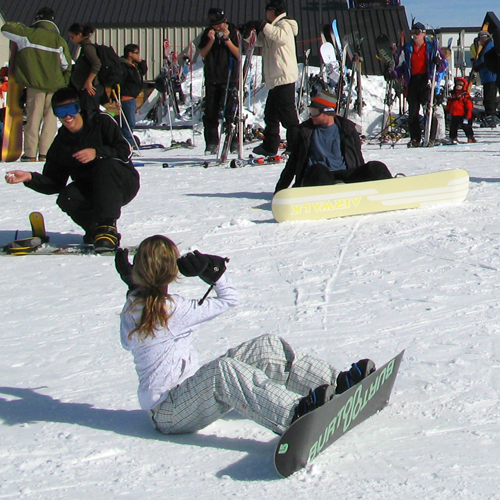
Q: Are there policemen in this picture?
A: No, there are no policemen.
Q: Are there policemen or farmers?
A: No, there are no policemen or farmers.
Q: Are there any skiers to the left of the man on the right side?
A: Yes, there is a skier to the left of the man.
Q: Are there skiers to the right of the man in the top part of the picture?
A: No, the skier is to the left of the man.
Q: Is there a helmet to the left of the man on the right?
A: No, there is a skier to the left of the man.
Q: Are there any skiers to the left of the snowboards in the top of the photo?
A: Yes, there is a skier to the left of the snowboards.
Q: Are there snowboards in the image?
A: Yes, there is a snowboard.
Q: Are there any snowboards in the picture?
A: Yes, there is a snowboard.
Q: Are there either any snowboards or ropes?
A: Yes, there is a snowboard.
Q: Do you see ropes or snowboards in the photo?
A: Yes, there is a snowboard.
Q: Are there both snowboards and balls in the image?
A: No, there is a snowboard but no balls.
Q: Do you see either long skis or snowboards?
A: Yes, there is a long snowboard.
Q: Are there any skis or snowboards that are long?
A: Yes, the snowboard is long.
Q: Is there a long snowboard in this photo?
A: Yes, there is a long snowboard.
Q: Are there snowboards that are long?
A: Yes, there is a snowboard that is long.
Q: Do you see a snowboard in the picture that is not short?
A: Yes, there is a long snowboard.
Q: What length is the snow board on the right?
A: The snowboard is long.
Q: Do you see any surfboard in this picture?
A: No, there are no surfboards.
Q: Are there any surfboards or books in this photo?
A: No, there are no surfboards or books.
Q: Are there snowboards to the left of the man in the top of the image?
A: Yes, there are snowboards to the left of the man.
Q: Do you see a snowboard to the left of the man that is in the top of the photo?
A: Yes, there are snowboards to the left of the man.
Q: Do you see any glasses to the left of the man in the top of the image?
A: No, there are snowboards to the left of the man.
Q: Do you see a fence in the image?
A: No, there are no fences.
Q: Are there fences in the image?
A: No, there are no fences.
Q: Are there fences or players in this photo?
A: No, there are no fences or players.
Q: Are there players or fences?
A: No, there are no fences or players.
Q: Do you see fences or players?
A: No, there are no fences or players.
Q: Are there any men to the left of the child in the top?
A: Yes, there is a man to the left of the child.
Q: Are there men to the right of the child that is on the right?
A: No, the man is to the left of the child.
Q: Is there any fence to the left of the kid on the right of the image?
A: No, there is a man to the left of the kid.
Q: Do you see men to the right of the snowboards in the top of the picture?
A: Yes, there is a man to the right of the snowboards.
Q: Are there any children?
A: Yes, there is a child.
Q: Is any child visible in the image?
A: Yes, there is a child.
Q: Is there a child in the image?
A: Yes, there is a child.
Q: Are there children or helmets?
A: Yes, there is a child.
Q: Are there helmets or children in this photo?
A: Yes, there is a child.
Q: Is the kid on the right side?
A: Yes, the kid is on the right of the image.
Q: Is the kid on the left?
A: No, the kid is on the right of the image.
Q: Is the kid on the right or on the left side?
A: The kid is on the right of the image.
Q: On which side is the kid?
A: The kid is on the right of the image.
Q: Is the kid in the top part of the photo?
A: Yes, the kid is in the top of the image.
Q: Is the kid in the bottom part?
A: No, the kid is in the top of the image.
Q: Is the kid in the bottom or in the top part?
A: The kid is in the top of the image.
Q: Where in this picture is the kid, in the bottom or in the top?
A: The kid is in the top of the image.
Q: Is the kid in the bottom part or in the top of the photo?
A: The kid is in the top of the image.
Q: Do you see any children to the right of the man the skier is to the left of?
A: Yes, there is a child to the right of the man.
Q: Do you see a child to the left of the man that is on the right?
A: No, the child is to the right of the man.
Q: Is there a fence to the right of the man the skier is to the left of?
A: No, there is a child to the right of the man.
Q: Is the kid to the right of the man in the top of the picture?
A: Yes, the kid is to the right of the man.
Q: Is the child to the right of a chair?
A: No, the child is to the right of the man.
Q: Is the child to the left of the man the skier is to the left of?
A: No, the child is to the right of the man.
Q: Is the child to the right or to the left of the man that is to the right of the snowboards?
A: The child is to the right of the man.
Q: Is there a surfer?
A: No, there are no surfers.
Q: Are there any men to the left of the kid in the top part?
A: Yes, there is a man to the left of the child.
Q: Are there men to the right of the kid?
A: No, the man is to the left of the kid.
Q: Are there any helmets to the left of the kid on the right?
A: No, there is a man to the left of the kid.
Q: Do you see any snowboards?
A: Yes, there is a snowboard.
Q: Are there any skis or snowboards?
A: Yes, there is a snowboard.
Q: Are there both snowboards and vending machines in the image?
A: No, there is a snowboard but no vending machines.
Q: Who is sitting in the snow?
A: The skier is sitting in the snow.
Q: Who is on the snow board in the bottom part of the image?
A: The skier is on the snowboard.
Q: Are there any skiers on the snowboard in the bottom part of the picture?
A: Yes, there is a skier on the snowboard.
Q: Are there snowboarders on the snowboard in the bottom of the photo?
A: No, there is a skier on the snowboard.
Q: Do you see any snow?
A: Yes, there is snow.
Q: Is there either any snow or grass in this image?
A: Yes, there is snow.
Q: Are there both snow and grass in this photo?
A: No, there is snow but no grass.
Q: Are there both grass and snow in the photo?
A: No, there is snow but no grass.